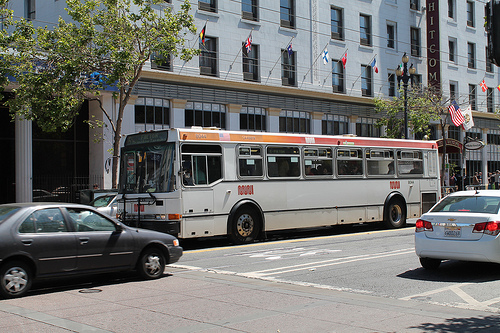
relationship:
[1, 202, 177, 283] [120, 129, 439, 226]
car and bus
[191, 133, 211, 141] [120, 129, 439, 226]
number on bus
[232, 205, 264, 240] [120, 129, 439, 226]
wheel on bus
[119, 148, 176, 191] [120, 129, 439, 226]
front window on bus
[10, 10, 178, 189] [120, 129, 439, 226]
tree in front of bus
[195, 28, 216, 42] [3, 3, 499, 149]
flag on building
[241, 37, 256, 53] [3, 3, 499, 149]
flag on building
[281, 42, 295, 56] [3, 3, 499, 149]
flag on building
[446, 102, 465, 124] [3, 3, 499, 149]
american flag on building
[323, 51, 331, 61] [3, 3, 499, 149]
flag on building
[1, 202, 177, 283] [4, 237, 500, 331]
car in street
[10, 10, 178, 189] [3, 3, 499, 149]
tree in front of building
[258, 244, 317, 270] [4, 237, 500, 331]
letters on road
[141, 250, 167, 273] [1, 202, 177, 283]
wheel of car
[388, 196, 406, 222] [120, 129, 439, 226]
tire on bus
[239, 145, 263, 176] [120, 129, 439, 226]
window on bus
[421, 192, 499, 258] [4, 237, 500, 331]
white car on street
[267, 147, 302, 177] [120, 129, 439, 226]
window on bus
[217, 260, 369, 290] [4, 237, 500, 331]
white marking on street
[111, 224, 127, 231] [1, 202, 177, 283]
side mirror on car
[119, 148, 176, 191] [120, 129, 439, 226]
front windshield on bus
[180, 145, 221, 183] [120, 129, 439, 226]
window on bus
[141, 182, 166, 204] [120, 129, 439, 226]
windshield wiper on bus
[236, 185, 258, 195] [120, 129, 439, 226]
red numbers on side of bus